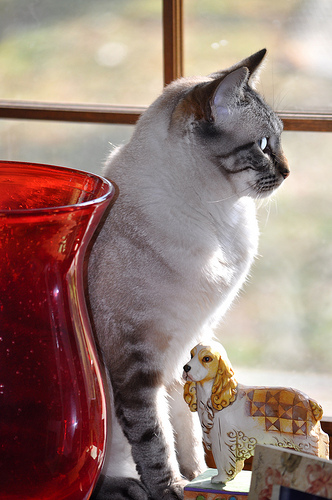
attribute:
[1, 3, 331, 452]
window — closed, clear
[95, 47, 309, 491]
cat — small, looking, white, grey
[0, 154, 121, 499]
vase — red, tall, big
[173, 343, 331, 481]
toy — white, brown